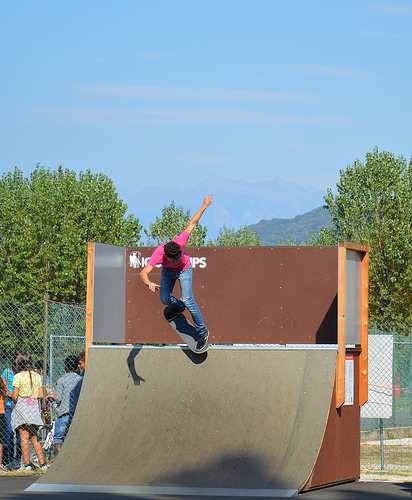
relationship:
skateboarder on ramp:
[136, 190, 220, 359] [25, 238, 373, 498]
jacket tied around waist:
[9, 395, 45, 429] [13, 388, 41, 407]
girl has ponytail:
[11, 349, 50, 476] [14, 346, 41, 391]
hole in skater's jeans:
[180, 291, 188, 307] [154, 266, 210, 343]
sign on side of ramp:
[344, 350, 357, 408] [299, 237, 371, 490]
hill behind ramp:
[234, 192, 336, 246] [25, 238, 373, 498]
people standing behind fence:
[2, 353, 85, 473] [0, 296, 411, 480]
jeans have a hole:
[154, 266, 210, 343] [180, 291, 188, 307]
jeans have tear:
[154, 266, 210, 343] [178, 293, 191, 307]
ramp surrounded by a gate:
[25, 238, 373, 498] [0, 296, 411, 480]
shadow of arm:
[122, 340, 149, 387] [138, 262, 162, 294]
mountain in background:
[234, 192, 336, 246] [2, 2, 407, 333]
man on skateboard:
[136, 190, 220, 359] [161, 304, 211, 356]